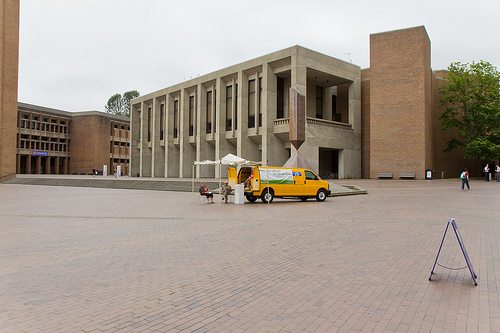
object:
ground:
[0, 173, 500, 333]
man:
[220, 181, 232, 204]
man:
[483, 164, 490, 183]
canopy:
[191, 152, 262, 206]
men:
[199, 180, 216, 204]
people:
[495, 164, 500, 183]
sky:
[17, 0, 500, 116]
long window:
[248, 75, 262, 128]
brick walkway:
[0, 173, 500, 333]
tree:
[104, 89, 140, 117]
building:
[0, 0, 129, 180]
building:
[129, 24, 500, 178]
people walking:
[459, 168, 471, 191]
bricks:
[0, 183, 500, 333]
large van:
[228, 165, 332, 204]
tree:
[434, 59, 500, 180]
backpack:
[460, 171, 468, 179]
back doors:
[236, 166, 252, 192]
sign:
[259, 168, 294, 185]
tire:
[316, 189, 327, 202]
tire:
[260, 188, 274, 204]